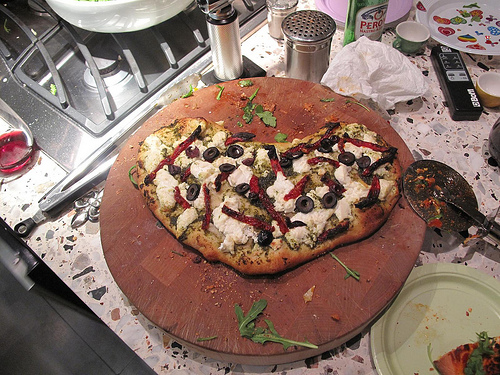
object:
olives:
[201, 141, 243, 173]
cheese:
[264, 170, 294, 211]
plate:
[367, 262, 498, 374]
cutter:
[394, 152, 499, 249]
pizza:
[130, 106, 410, 282]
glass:
[1, 99, 45, 202]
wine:
[1, 129, 38, 177]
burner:
[2, 2, 264, 135]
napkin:
[318, 32, 434, 111]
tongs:
[33, 97, 170, 214]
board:
[91, 73, 436, 371]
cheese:
[336, 162, 363, 215]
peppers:
[249, 180, 288, 232]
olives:
[294, 187, 341, 218]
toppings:
[163, 137, 385, 228]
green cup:
[390, 20, 432, 62]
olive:
[234, 175, 260, 205]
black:
[234, 180, 256, 200]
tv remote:
[426, 43, 484, 126]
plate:
[413, 0, 499, 60]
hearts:
[430, 13, 481, 48]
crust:
[349, 210, 389, 241]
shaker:
[264, 1, 297, 38]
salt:
[263, 17, 283, 42]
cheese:
[192, 158, 219, 179]